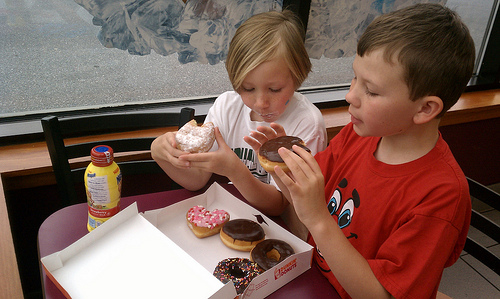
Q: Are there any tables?
A: Yes, there is a table.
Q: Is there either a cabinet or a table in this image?
A: Yes, there is a table.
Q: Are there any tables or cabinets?
A: Yes, there is a table.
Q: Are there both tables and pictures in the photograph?
A: No, there is a table but no pictures.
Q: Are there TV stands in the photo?
A: No, there are no TV stands.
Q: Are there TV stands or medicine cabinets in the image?
A: No, there are no TV stands or medicine cabinets.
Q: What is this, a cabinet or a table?
A: This is a table.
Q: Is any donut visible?
A: Yes, there is a donut.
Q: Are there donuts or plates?
A: Yes, there is a donut.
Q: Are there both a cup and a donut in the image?
A: No, there is a donut but no cups.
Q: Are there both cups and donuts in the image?
A: No, there is a donut but no cups.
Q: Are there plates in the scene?
A: No, there are no plates.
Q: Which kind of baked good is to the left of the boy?
A: The food is a donut.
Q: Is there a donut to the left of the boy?
A: Yes, there is a donut to the left of the boy.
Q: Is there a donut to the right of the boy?
A: No, the donut is to the left of the boy.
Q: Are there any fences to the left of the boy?
A: No, there is a donut to the left of the boy.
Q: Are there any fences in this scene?
A: No, there are no fences.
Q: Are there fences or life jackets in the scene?
A: No, there are no fences or life jackets.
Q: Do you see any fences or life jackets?
A: No, there are no fences or life jackets.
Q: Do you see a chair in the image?
A: Yes, there is a chair.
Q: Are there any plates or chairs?
A: Yes, there is a chair.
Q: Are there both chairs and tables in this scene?
A: Yes, there are both a chair and a table.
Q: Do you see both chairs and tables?
A: Yes, there are both a chair and a table.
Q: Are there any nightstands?
A: No, there are no nightstands.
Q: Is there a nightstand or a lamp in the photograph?
A: No, there are no nightstands or lamps.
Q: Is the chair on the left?
A: Yes, the chair is on the left of the image.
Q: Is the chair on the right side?
A: No, the chair is on the left of the image.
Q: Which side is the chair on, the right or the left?
A: The chair is on the left of the image.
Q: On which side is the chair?
A: The chair is on the left of the image.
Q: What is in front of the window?
A: The chair is in front of the window.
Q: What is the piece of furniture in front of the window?
A: The piece of furniture is a chair.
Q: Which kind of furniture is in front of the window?
A: The piece of furniture is a chair.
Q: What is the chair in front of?
A: The chair is in front of the window.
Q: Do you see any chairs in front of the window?
A: Yes, there is a chair in front of the window.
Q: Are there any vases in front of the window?
A: No, there is a chair in front of the window.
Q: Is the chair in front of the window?
A: Yes, the chair is in front of the window.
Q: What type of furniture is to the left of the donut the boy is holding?
A: The piece of furniture is a chair.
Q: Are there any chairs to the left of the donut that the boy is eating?
A: Yes, there is a chair to the left of the donut.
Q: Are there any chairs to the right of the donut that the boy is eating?
A: No, the chair is to the left of the doughnut.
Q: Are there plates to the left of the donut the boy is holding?
A: No, there is a chair to the left of the donut.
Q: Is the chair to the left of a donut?
A: Yes, the chair is to the left of a donut.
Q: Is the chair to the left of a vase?
A: No, the chair is to the left of a donut.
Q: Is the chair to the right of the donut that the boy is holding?
A: No, the chair is to the left of the doughnut.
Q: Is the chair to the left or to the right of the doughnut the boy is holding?
A: The chair is to the left of the doughnut.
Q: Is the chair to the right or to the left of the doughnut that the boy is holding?
A: The chair is to the left of the doughnut.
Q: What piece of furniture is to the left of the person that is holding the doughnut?
A: The piece of furniture is a chair.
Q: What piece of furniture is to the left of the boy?
A: The piece of furniture is a chair.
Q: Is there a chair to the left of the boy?
A: Yes, there is a chair to the left of the boy.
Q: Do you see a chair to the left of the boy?
A: Yes, there is a chair to the left of the boy.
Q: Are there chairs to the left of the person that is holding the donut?
A: Yes, there is a chair to the left of the boy.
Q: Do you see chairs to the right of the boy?
A: No, the chair is to the left of the boy.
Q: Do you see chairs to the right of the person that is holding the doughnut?
A: No, the chair is to the left of the boy.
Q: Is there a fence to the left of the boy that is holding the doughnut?
A: No, there is a chair to the left of the boy.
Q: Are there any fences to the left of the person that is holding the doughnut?
A: No, there is a chair to the left of the boy.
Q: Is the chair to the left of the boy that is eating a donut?
A: Yes, the chair is to the left of the boy.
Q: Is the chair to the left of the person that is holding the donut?
A: Yes, the chair is to the left of the boy.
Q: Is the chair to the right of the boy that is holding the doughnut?
A: No, the chair is to the left of the boy.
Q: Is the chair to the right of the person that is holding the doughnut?
A: No, the chair is to the left of the boy.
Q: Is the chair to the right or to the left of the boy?
A: The chair is to the left of the boy.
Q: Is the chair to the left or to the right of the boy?
A: The chair is to the left of the boy.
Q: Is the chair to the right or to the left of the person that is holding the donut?
A: The chair is to the left of the boy.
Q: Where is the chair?
A: The chair is at the table.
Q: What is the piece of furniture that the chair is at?
A: The piece of furniture is a table.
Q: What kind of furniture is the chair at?
A: The chair is at the table.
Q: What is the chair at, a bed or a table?
A: The chair is at a table.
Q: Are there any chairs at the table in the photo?
A: Yes, there is a chair at the table.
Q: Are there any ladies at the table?
A: No, there is a chair at the table.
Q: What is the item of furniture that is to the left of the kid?
A: The piece of furniture is a chair.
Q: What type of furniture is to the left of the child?
A: The piece of furniture is a chair.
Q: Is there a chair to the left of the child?
A: Yes, there is a chair to the left of the child.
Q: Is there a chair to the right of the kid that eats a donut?
A: No, the chair is to the left of the kid.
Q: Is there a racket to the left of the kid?
A: No, there is a chair to the left of the kid.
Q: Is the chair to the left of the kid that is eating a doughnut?
A: Yes, the chair is to the left of the kid.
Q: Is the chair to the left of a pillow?
A: No, the chair is to the left of the kid.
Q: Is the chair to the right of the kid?
A: No, the chair is to the left of the kid.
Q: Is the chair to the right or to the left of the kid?
A: The chair is to the left of the kid.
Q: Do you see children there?
A: Yes, there is a child.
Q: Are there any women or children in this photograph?
A: Yes, there is a child.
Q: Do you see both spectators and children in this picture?
A: No, there is a child but no spectators.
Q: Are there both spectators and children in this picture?
A: No, there is a child but no spectators.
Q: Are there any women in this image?
A: No, there are no women.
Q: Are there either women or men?
A: No, there are no women or men.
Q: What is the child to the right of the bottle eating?
A: The child is eating a donut.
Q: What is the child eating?
A: The child is eating a donut.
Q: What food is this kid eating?
A: The kid is eating a doughnut.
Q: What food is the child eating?
A: The kid is eating a doughnut.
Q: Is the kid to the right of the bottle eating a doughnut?
A: Yes, the child is eating a doughnut.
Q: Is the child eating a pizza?
A: No, the child is eating a doughnut.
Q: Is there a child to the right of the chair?
A: Yes, there is a child to the right of the chair.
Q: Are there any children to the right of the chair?
A: Yes, there is a child to the right of the chair.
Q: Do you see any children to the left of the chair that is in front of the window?
A: No, the child is to the right of the chair.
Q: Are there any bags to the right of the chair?
A: No, there is a child to the right of the chair.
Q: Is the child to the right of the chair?
A: Yes, the child is to the right of the chair.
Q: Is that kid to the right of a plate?
A: No, the kid is to the right of the chair.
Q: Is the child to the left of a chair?
A: No, the child is to the right of a chair.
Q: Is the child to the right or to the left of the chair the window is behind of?
A: The child is to the right of the chair.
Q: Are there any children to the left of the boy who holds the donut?
A: Yes, there is a child to the left of the boy.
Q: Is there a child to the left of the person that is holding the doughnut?
A: Yes, there is a child to the left of the boy.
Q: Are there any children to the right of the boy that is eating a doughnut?
A: No, the child is to the left of the boy.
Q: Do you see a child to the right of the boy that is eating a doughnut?
A: No, the child is to the left of the boy.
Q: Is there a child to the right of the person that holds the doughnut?
A: No, the child is to the left of the boy.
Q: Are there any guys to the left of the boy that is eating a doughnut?
A: No, there is a child to the left of the boy.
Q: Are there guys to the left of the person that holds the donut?
A: No, there is a child to the left of the boy.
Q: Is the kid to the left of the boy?
A: Yes, the kid is to the left of the boy.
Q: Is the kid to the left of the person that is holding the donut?
A: Yes, the kid is to the left of the boy.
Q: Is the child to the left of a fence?
A: No, the child is to the left of the boy.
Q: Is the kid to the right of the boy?
A: No, the kid is to the left of the boy.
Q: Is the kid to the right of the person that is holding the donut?
A: No, the kid is to the left of the boy.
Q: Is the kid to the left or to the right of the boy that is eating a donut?
A: The kid is to the left of the boy.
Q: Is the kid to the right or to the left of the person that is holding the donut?
A: The kid is to the left of the boy.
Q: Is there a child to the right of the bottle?
A: Yes, there is a child to the right of the bottle.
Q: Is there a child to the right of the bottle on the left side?
A: Yes, there is a child to the right of the bottle.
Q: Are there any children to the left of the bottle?
A: No, the child is to the right of the bottle.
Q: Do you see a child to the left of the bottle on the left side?
A: No, the child is to the right of the bottle.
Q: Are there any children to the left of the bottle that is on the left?
A: No, the child is to the right of the bottle.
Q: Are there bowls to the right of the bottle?
A: No, there is a child to the right of the bottle.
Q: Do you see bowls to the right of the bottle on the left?
A: No, there is a child to the right of the bottle.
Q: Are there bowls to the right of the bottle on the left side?
A: No, there is a child to the right of the bottle.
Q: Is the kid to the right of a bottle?
A: Yes, the kid is to the right of a bottle.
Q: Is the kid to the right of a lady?
A: No, the kid is to the right of a bottle.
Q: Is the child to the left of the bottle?
A: No, the child is to the right of the bottle.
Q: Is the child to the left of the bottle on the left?
A: No, the child is to the right of the bottle.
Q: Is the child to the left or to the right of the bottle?
A: The child is to the right of the bottle.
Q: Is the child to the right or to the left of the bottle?
A: The child is to the right of the bottle.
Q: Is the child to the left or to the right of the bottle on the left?
A: The child is to the right of the bottle.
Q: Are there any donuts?
A: Yes, there is a donut.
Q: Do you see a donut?
A: Yes, there is a donut.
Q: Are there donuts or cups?
A: Yes, there is a donut.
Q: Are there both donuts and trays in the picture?
A: No, there is a donut but no trays.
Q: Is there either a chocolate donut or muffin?
A: Yes, there is a chocolate donut.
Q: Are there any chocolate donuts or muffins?
A: Yes, there is a chocolate donut.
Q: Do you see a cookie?
A: No, there are no cookies.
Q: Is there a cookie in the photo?
A: No, there are no cookies.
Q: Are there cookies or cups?
A: No, there are no cookies or cups.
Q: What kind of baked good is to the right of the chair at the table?
A: The food is a donut.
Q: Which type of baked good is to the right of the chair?
A: The food is a donut.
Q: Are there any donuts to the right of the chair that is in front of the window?
A: Yes, there is a donut to the right of the chair.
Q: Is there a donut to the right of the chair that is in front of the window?
A: Yes, there is a donut to the right of the chair.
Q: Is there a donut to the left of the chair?
A: No, the donut is to the right of the chair.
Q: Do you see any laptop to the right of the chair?
A: No, there is a donut to the right of the chair.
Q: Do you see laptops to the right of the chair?
A: No, there is a donut to the right of the chair.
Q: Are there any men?
A: No, there are no men.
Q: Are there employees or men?
A: No, there are no men or employees.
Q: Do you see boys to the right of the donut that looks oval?
A: Yes, there is a boy to the right of the donut.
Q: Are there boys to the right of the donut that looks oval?
A: Yes, there is a boy to the right of the donut.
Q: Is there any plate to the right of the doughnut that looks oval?
A: No, there is a boy to the right of the donut.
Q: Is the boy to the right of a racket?
A: No, the boy is to the right of the doughnut.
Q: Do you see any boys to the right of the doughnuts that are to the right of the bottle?
A: Yes, there is a boy to the right of the donuts.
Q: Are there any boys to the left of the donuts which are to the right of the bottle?
A: No, the boy is to the right of the donuts.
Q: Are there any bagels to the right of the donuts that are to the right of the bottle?
A: No, there is a boy to the right of the donuts.